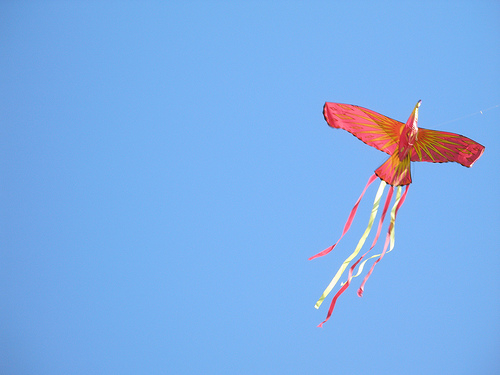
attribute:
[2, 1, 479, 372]
sky — blue, clear, crystal clear, cloudless, sunny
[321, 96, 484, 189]
kite — yellow, red, bird, firey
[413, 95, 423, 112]
end — yellow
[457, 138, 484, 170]
wing — bent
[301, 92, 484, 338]
kite — bird, large, red, yellow, bird shaped, pink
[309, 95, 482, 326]
kite — bird, sheer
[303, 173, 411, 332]
ribbons — yellow, red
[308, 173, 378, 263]
string — red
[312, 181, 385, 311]
string — yellow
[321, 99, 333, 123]
tip — black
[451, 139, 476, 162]
design — red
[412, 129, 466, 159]
design — pink, orange, yellow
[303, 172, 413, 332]
streamers — pink, white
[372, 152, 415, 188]
tail — pink, yellow, orange